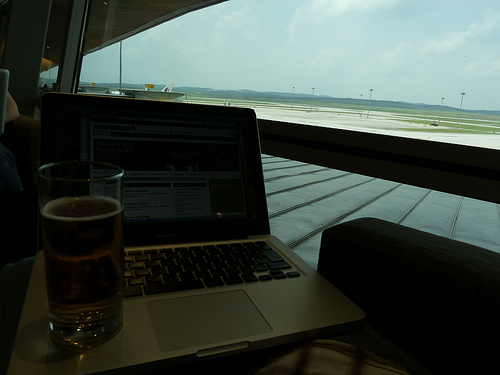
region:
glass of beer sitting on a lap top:
[17, 148, 136, 361]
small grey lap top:
[15, 80, 374, 370]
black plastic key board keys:
[90, 223, 304, 314]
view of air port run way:
[88, 71, 498, 152]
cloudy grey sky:
[73, 3, 498, 125]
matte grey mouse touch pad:
[128, 284, 278, 361]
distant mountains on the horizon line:
[80, 73, 498, 122]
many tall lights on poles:
[261, 80, 472, 145]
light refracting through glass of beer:
[0, 304, 132, 367]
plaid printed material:
[261, 313, 426, 374]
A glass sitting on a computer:
[30, 155, 127, 353]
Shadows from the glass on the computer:
[10, 316, 128, 358]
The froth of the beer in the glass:
[42, 196, 123, 228]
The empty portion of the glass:
[39, 165, 123, 216]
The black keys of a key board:
[50, 245, 297, 285]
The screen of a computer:
[33, 96, 267, 246]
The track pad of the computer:
[145, 286, 275, 351]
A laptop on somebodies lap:
[42, 86, 370, 371]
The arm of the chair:
[305, 215, 492, 356]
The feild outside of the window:
[126, 62, 498, 157]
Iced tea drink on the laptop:
[33, 153, 127, 350]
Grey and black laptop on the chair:
[5, 89, 372, 374]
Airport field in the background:
[39, 1, 498, 151]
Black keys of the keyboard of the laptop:
[117, 236, 300, 300]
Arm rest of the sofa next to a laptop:
[317, 213, 498, 373]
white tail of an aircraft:
[158, 81, 176, 93]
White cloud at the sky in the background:
[385, 10, 494, 68]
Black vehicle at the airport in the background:
[427, 121, 443, 128]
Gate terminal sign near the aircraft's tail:
[142, 81, 155, 90]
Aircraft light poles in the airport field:
[283, 83, 469, 130]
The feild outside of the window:
[217, 83, 497, 137]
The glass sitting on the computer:
[43, 143, 128, 346]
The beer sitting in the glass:
[46, 201, 121, 345]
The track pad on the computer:
[142, 286, 270, 351]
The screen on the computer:
[51, 106, 253, 228]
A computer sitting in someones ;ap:
[38, 91, 357, 371]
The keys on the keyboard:
[44, 246, 300, 298]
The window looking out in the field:
[86, 1, 494, 163]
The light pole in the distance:
[457, 86, 464, 129]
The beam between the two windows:
[54, 4, 88, 94]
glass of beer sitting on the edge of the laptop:
[39, 162, 125, 348]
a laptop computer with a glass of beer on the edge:
[8, 93, 368, 373]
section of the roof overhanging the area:
[4, 0, 226, 75]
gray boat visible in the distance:
[116, 83, 184, 100]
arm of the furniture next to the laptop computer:
[318, 217, 499, 369]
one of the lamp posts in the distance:
[455, 93, 464, 126]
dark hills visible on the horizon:
[61, 84, 499, 115]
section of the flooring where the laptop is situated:
[266, 153, 494, 230]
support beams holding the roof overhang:
[33, 3, 85, 93]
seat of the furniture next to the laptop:
[251, 343, 410, 373]